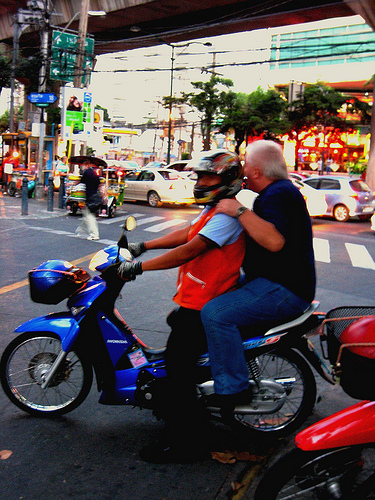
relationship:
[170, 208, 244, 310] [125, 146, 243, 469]
vest on man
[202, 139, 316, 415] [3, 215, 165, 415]
man riding motorbike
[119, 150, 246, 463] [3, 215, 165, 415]
man riding motorbike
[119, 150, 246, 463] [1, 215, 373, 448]
man on motorbike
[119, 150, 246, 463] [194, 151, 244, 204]
man wears helmet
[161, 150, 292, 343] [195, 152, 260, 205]
man has helmet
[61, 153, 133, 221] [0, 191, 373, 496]
food cart on street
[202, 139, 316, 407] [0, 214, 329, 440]
man on bike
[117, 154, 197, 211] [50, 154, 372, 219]
cars waiting in traffic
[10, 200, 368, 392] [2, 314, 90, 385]
bike has tire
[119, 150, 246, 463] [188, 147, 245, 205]
man wearing helmet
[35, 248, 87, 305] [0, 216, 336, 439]
basket on motorcycle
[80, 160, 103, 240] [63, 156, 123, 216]
man attending food cart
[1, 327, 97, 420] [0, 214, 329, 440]
tire on bike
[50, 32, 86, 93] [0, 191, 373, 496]
sign hanging over street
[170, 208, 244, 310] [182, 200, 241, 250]
vest over shirt